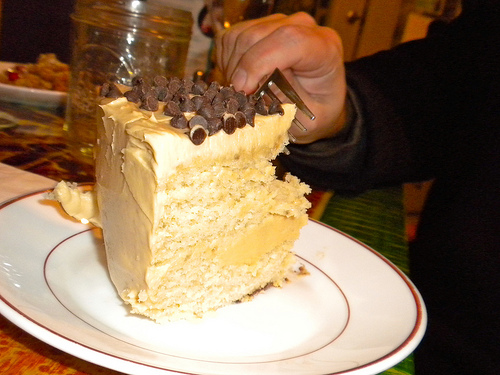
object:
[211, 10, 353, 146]
hand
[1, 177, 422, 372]
plate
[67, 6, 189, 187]
jar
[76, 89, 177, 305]
icing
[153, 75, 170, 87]
chips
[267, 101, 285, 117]
chip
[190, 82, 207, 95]
chip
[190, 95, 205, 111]
chip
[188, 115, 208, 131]
chip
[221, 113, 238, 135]
chip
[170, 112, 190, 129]
chip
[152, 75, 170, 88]
chip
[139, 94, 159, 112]
chip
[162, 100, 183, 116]
chip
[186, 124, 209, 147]
chip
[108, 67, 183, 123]
pieces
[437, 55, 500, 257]
black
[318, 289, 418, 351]
boarder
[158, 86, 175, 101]
chips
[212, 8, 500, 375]
person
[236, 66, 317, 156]
fork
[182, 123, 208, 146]
chips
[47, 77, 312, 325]
cake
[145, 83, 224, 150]
kisses